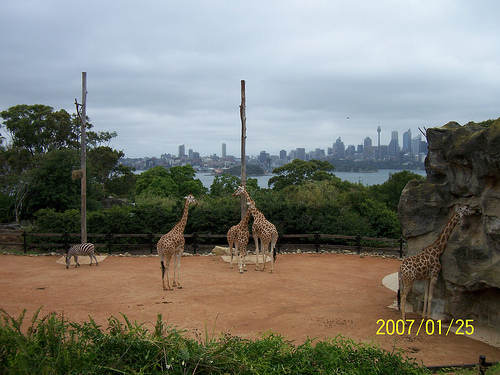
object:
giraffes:
[155, 193, 203, 291]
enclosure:
[0, 232, 490, 372]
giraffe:
[394, 202, 480, 325]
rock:
[394, 121, 498, 319]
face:
[389, 114, 497, 338]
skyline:
[118, 124, 424, 165]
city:
[127, 131, 437, 170]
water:
[201, 167, 414, 189]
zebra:
[66, 243, 99, 269]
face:
[65, 258, 70, 269]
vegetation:
[299, 331, 346, 375]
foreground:
[16, 311, 493, 362]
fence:
[0, 228, 405, 257]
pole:
[237, 80, 251, 250]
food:
[215, 245, 275, 264]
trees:
[133, 164, 177, 198]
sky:
[4, 8, 496, 140]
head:
[65, 256, 70, 269]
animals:
[158, 192, 200, 291]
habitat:
[7, 8, 494, 372]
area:
[7, 248, 483, 372]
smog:
[19, 14, 497, 126]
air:
[0, 2, 500, 371]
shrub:
[356, 198, 396, 236]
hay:
[71, 169, 87, 182]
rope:
[80, 72, 87, 244]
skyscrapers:
[403, 128, 411, 154]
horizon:
[14, 110, 495, 175]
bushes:
[288, 197, 380, 238]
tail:
[396, 270, 403, 309]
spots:
[418, 262, 422, 267]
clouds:
[0, 10, 489, 123]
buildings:
[391, 128, 398, 162]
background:
[3, 4, 481, 157]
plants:
[0, 101, 101, 219]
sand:
[6, 253, 395, 346]